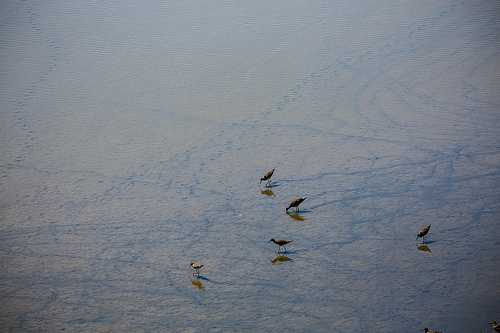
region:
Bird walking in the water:
[216, 166, 376, 293]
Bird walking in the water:
[177, 248, 213, 284]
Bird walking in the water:
[415, 225, 444, 244]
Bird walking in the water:
[258, 222, 297, 262]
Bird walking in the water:
[272, 197, 316, 228]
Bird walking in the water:
[253, 163, 282, 195]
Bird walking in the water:
[290, 193, 302, 223]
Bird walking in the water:
[404, 218, 437, 251]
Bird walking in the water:
[248, 157, 290, 206]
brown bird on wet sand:
[416, 213, 439, 252]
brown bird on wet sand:
[267, 234, 297, 255]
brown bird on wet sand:
[167, 249, 226, 293]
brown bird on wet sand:
[292, 194, 318, 217]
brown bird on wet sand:
[248, 162, 281, 200]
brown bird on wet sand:
[180, 237, 218, 283]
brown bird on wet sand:
[194, 218, 232, 253]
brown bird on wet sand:
[75, 223, 123, 258]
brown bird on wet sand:
[179, 171, 226, 215]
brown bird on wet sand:
[319, 257, 347, 296]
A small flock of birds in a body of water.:
[191, 148, 439, 298]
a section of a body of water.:
[46, 65, 196, 137]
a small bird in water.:
[406, 212, 447, 253]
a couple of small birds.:
[261, 185, 323, 268]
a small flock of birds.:
[255, 156, 312, 267]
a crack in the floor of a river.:
[179, 88, 284, 160]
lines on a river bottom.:
[146, 142, 213, 248]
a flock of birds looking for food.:
[72, 89, 446, 328]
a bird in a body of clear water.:
[246, 158, 277, 192]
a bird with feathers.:
[403, 220, 440, 252]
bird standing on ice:
[248, 155, 285, 206]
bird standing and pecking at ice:
[246, 156, 288, 208]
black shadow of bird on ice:
[253, 184, 285, 202]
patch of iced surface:
[11, 194, 178, 331]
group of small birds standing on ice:
[148, 152, 450, 287]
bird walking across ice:
[258, 229, 301, 269]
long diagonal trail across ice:
[112, 0, 457, 245]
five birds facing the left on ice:
[165, 150, 453, 305]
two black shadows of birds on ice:
[253, 184, 313, 229]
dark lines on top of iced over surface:
[42, 234, 184, 331]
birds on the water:
[173, 250, 210, 284]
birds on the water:
[402, 198, 441, 249]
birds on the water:
[253, 226, 293, 263]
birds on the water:
[273, 178, 312, 236]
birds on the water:
[232, 133, 327, 298]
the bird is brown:
[190, 261, 211, 282]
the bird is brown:
[254, 225, 323, 270]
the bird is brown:
[279, 176, 306, 225]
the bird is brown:
[238, 149, 294, 200]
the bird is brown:
[408, 215, 445, 274]